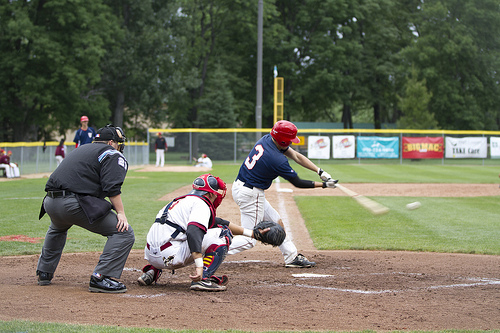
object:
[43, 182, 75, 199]
belt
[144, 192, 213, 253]
shirt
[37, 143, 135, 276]
clothing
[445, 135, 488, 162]
banner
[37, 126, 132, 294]
man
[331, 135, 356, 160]
banner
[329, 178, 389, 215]
baseball bat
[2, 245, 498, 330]
dirt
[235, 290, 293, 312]
indention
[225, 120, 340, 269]
man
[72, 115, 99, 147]
man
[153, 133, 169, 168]
man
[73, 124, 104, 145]
shirt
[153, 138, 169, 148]
shirt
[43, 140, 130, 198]
shirt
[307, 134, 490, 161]
advertisements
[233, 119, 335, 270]
hitter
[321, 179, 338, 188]
hand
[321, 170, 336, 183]
hand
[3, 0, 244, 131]
trees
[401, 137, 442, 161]
banner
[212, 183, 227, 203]
face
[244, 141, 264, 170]
3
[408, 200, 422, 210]
baseball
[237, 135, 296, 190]
jersey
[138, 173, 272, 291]
catcher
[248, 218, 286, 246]
catcher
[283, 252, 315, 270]
shoe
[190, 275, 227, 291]
shoe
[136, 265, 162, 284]
shoe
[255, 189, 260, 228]
stripe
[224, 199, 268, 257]
leg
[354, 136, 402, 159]
banner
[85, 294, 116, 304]
indentations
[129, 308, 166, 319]
indentations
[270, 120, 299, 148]
helmet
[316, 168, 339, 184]
gloves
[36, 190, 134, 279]
pants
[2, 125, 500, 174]
fence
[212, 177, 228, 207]
mask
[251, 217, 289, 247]
mitt